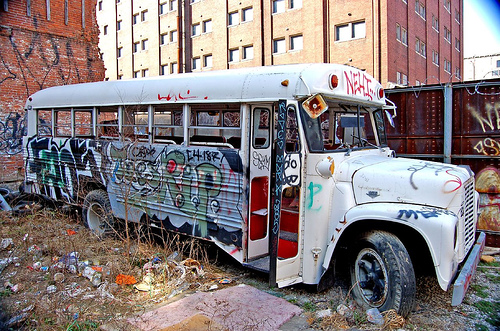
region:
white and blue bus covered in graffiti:
[9, 60, 486, 314]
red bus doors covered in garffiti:
[236, 94, 308, 293]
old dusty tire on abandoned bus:
[352, 231, 414, 327]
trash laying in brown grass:
[11, 218, 206, 328]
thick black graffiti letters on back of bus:
[21, 130, 118, 216]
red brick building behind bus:
[4, 0, 106, 196]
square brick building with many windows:
[96, 0, 486, 88]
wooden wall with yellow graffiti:
[379, 78, 499, 266]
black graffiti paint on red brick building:
[5, 28, 105, 104]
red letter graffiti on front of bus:
[337, 68, 377, 105]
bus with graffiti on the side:
[25, 66, 482, 315]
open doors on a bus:
[245, 101, 312, 288]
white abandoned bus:
[24, 79, 477, 309]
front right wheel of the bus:
[350, 222, 418, 322]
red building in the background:
[83, 0, 471, 87]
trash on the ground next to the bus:
[1, 200, 231, 327]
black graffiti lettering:
[29, 133, 104, 214]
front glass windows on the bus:
[303, 106, 385, 153]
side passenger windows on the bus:
[33, 102, 250, 138]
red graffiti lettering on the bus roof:
[341, 72, 376, 97]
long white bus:
[12, 60, 492, 329]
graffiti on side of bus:
[26, 139, 247, 251]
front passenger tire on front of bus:
[338, 223, 424, 327]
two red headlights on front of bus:
[320, 71, 386, 101]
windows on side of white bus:
[31, 98, 245, 153]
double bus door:
[237, 97, 309, 290]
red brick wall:
[4, 24, 110, 196]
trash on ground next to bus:
[3, 232, 219, 329]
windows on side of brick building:
[98, 0, 468, 85]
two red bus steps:
[254, 195, 307, 275]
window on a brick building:
[331, 20, 370, 40]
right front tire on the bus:
[346, 225, 417, 321]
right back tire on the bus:
[80, 184, 117, 235]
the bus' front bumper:
[449, 230, 489, 307]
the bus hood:
[349, 155, 479, 257]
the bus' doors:
[241, 100, 311, 290]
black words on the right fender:
[392, 207, 461, 229]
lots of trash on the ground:
[1, 221, 217, 329]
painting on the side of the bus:
[22, 135, 256, 242]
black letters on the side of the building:
[0, 24, 102, 85]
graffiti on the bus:
[21, 77, 255, 263]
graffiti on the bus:
[57, 133, 231, 210]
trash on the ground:
[50, 226, 137, 302]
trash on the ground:
[58, 228, 203, 307]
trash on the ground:
[23, 224, 98, 326]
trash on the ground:
[83, 237, 144, 282]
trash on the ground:
[116, 240, 232, 309]